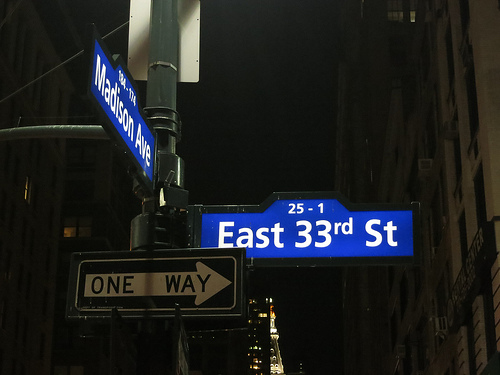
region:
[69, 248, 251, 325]
The one way sign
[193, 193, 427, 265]
Sign that says east 33rd st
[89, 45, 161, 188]
The madison ave sign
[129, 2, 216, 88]
The sign that we can only see the back of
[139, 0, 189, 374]
The pole holding the signs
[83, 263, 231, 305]
The white arrow on the one way sign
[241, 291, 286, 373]
The building with lights on in the background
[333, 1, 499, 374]
The buildings to the right of the signs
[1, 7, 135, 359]
The building to the left of the signs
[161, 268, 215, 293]
The word 'way' written in black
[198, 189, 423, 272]
blue and white sign for East 33rd st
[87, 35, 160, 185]
blue and white sign for madison ave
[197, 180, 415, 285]
street sign notating 25-1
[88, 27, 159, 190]
street sign notating 134-174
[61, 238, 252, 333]
black and white sign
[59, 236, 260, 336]
one way sign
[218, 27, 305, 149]
black night time sky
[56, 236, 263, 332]
black and white sign with an arrow pointing right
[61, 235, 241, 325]
black and white sign that says one way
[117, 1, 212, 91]
Back of a sign above the Madison Ave sign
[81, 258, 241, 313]
Black and white street sign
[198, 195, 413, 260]
Blue and white street sign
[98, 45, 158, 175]
Blue and white avenue sign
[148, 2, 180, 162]
Metal city street pole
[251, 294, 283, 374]
City traffic urban street scene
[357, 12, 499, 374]
Large stone city building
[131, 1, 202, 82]
Silver street sign marker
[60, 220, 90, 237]
Lit city window scene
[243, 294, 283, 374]
Night time traffic scene in city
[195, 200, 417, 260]
Updated city lit street signs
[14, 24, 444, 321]
madison ave street sign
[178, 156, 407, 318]
33rd street sign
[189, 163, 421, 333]
east 33rd street in new york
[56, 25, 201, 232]
madison avenue in new york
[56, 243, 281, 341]
one way street in new york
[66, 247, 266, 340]
one way street sign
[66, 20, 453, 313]
intersection of madison and 33rd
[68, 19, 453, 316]
madison and east 33rd intersection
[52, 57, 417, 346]
cross streets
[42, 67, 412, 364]
new york city streets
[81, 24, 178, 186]
Street sign on a pole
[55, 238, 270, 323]
One way street sign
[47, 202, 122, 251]
Lights showing through building windows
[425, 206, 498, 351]
Sign on a building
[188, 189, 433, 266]
A sign designating East 33rd Street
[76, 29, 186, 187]
A sign designating Madison Avenue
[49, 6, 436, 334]
Directional and street markers sign on a pole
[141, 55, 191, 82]
A strap to hold a sign on the pole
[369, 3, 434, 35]
Lights shining through top of building windows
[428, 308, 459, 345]
A window air conditioner